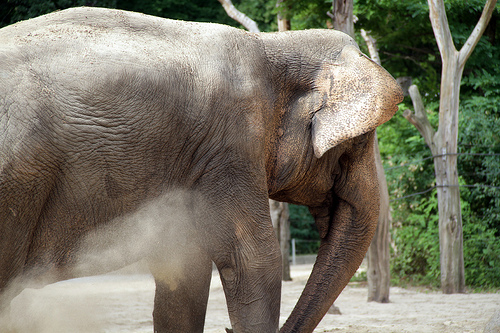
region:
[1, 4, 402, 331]
an asian elephant in it's enclosure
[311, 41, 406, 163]
an asian eloephant has shorter ears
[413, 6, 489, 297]
tree without bark has a smooth surface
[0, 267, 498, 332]
ground is all dirt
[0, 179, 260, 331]
cloud of dust from the ground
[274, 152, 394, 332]
elephant trunk is bent under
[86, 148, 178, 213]
a spot on the side of the elephant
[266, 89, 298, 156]
looks like warts on the elephant neck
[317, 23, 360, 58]
knob on the elephant's head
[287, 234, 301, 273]
a steel post in the ground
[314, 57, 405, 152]
a floppy gray ear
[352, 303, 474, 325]
gray dirt on the ground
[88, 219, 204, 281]
a cloud of dust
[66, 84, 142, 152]
gray wrinkled skin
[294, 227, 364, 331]
a long thick gray trunk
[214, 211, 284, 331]
a huge gray leg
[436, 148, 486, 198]
black rope around the tree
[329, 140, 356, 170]
a black eye in a head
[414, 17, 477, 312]
a bare gray tree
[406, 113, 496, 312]
thick green bushes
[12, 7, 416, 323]
ah elephant walking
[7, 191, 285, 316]
the elephant has kicked up some dust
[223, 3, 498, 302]
a few trees are in front of the elephant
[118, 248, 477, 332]
the ground is covered in dirt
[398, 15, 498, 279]
many green leaves are in this area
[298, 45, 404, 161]
the back of the elephants ear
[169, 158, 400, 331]
the elephants trunk is kicking up the dust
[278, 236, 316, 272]
a small portion of the fence can be seen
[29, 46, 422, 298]
the elephant is grey in color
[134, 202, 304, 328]
both of the elephants front legs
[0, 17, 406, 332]
this is an elephant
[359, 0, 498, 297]
this is a bark of a tree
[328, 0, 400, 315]
this is a bark of a tree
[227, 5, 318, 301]
this is a bark of a tree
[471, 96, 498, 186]
this is a branch of a tree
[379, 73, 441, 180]
this is a branch of a tree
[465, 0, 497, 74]
this is a branch of a tree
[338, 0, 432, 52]
this is a branch of a tree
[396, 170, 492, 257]
this is a branch of a tree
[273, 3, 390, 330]
Head of an elephant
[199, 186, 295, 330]
Leg of an elephant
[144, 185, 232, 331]
Leg of an elephant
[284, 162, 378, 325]
Trunk of an elephant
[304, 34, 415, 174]
Ear of an elephant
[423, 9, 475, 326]
Leg of a tree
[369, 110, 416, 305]
Leg of a tree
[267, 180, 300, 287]
Leg of a tree